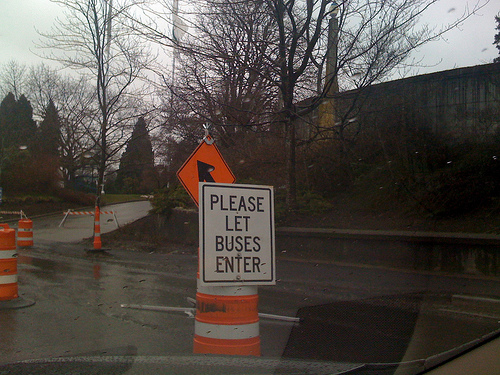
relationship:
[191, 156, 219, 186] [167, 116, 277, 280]
arrow on traffic sign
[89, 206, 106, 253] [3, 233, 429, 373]
cone in street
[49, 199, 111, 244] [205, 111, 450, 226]
cement on hill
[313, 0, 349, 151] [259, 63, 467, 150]
post on wall